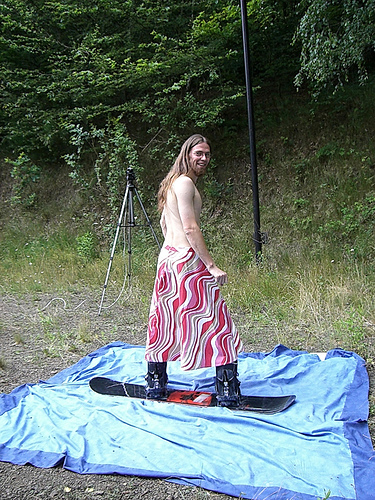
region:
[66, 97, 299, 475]
a man with a skirt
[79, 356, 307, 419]
a black and red snow board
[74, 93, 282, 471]
a man on a snowboard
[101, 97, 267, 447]
a man with long hair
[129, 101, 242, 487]
a man with a beard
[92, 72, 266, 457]
a man with no shirt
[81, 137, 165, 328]
a camera on a tripod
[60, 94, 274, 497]
a mon on a blue tarp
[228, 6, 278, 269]
a black pole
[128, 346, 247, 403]
black snowboard boots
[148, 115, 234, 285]
The man has hair.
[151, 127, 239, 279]
The man's hair is long.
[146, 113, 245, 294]
The man is shirtless.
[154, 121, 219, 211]
The man has a beard.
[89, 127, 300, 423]
The man is standing on a snowboard.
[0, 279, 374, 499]
A blanket is lying on the ground.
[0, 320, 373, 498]
The blanket is two-tone.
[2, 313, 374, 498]
The blanket is blue.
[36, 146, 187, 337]
A tripos is set up.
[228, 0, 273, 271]
The pole is black.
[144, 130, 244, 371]
Man wearing a colorful skirt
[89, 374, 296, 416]
Black and orange snowboard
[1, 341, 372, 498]
Blue blanket on the ground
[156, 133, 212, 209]
Man with long brown hair and glasses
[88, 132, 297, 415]
Man riding a snowboard on a blanket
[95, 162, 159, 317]
Tripod standing on the ground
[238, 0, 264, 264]
Black steel post in the ground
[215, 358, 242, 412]
Black snowboard boot on man's foot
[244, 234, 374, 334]
Tall tan and green grass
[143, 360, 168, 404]
Black snowboard boot on man's foot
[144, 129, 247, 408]
the man is shirtless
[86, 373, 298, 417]
the snowboard is black and red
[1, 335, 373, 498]
the man is using this blue blanket to protect the snowboard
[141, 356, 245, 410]
the boots are black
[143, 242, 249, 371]
the man is wearing a red, pink, grey and white skirt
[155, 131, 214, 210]
the man has long hair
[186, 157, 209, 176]
the man is has a beard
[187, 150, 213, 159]
the man is wearing glasses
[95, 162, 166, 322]
this tripod has a video camera on top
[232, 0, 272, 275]
the large poll is painted black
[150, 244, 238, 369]
A skirt in the photo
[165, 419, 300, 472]
A mat on the floor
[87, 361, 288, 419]
A surf board in the board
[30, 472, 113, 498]
Sand on the ground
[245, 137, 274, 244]
A pole in the photo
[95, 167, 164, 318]
A camera stand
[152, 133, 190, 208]
Long blonde hair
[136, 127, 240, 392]
bare-chested man standing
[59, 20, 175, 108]
Trees in the photo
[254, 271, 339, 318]
Grass in the photo